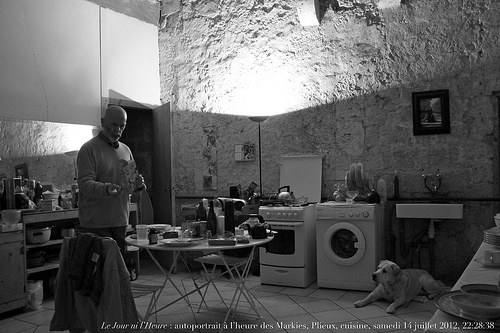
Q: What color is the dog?
A: Brown.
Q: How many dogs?
A: One.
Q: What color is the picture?
A: Black and white.